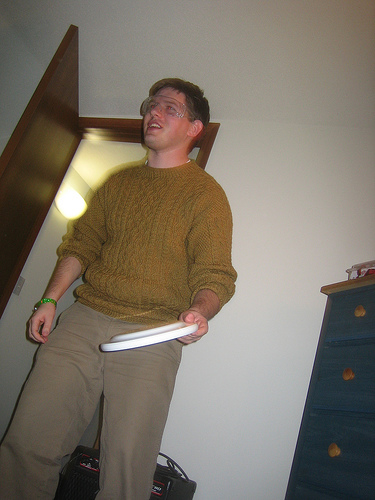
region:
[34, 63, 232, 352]
man in a yellow sweater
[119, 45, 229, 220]
man wearing safety goggles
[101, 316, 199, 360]
white plastic frisbee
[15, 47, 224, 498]
man holding a frisbee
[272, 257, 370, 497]
blue wooden dresser with brown knobs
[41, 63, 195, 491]
man in tan pants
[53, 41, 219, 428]
man standing near an open doorway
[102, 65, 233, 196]
man with brown hair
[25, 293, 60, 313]
bright green wrist watch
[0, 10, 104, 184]
open brown wooden door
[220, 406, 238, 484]
The white wall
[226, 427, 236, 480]
The white wall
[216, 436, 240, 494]
The white wall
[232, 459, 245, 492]
The white wall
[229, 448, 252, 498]
The white wall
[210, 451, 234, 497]
The white wall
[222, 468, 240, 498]
The white wall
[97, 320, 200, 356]
A white firsbee.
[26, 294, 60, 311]
A green bracelet.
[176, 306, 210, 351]
The hand holds the frisbee.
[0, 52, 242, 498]
A man standing up.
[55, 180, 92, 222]
A wall light is on.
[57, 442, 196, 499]
An amp in the background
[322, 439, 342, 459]
A knob for a handle.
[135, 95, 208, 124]
A clear pair of googles.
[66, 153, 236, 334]
A mustard colored sweater.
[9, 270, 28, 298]
A light switch on wall.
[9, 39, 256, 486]
Man holding a frisbee.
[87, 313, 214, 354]
A white frisbee.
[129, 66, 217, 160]
A pair of safety glasses.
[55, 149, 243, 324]
A long sleeve sweater.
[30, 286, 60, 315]
Green band around right wrist.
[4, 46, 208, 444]
A open doorway.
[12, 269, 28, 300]
A light switch on the wall.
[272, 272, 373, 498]
A blue chest of drawers.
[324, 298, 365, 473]
Three brown knobs on chest of drawers.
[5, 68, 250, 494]
Man wearing a pair of long pants.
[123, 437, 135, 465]
man wearing khaki pants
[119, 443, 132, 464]
man wearing khaki pants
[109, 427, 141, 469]
man wearing khaki pants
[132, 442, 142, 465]
man wearing khaki pants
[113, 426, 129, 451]
man wearing khaki pants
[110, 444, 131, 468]
man wearing khaki pants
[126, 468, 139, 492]
man wearing khaki pants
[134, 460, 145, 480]
man wearing khaki pants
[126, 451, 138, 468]
man wearing khaki pants